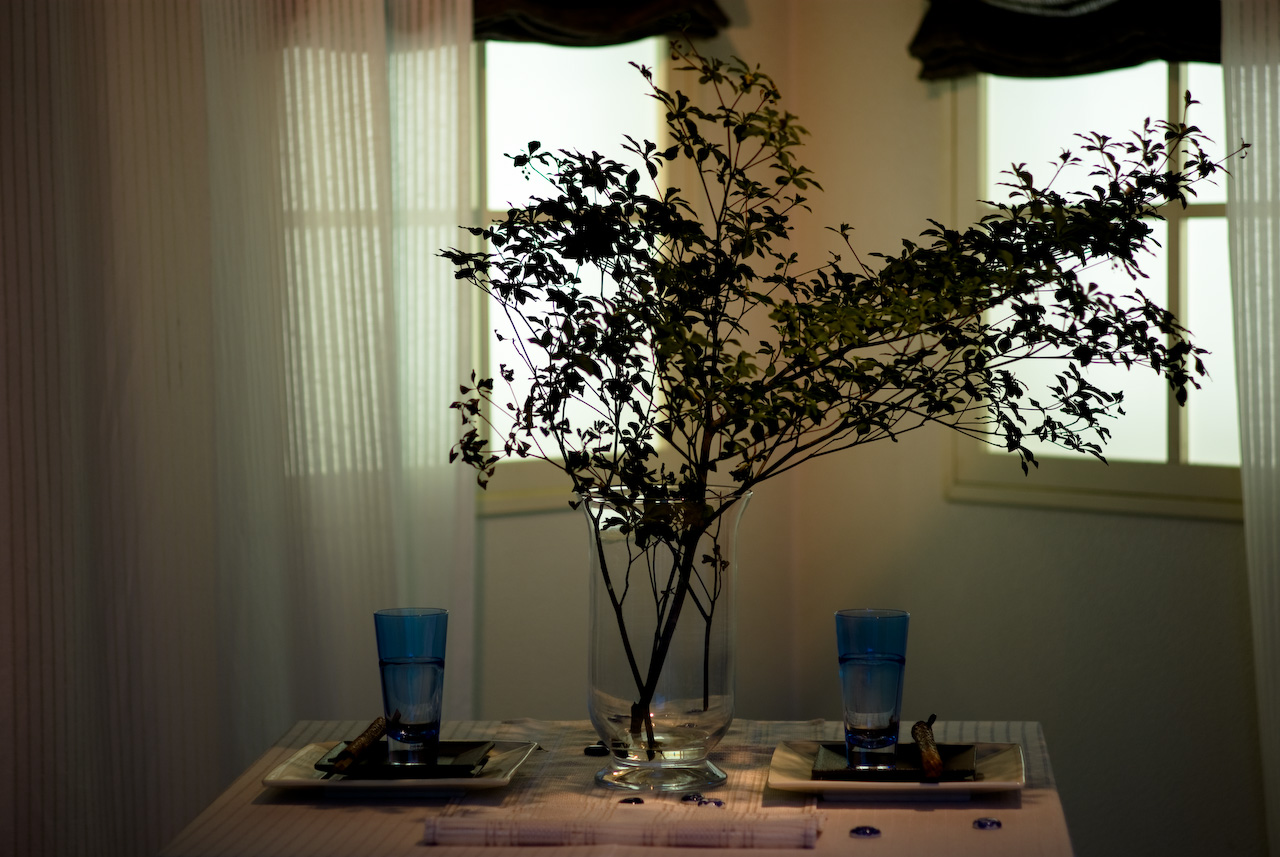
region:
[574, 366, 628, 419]
leaf on the plant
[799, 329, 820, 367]
leaf on the plant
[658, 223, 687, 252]
leaf on the plant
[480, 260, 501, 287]
leaf on the plant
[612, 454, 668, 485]
leaf on the plant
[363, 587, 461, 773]
blue glass on the tray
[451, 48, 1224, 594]
tree in a vase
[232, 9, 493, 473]
sheer white curtain on the window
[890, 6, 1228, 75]
valance on top of the window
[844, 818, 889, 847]
purple rock on the table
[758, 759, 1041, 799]
white tray on the table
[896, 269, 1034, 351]
leaves on the tree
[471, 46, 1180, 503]
picture taken during the day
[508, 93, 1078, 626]
tree stems in the vase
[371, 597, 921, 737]
two blue glasses on the table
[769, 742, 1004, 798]
the plates are square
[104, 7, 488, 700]
white long curtains hang in front of the window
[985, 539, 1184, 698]
the wall is white in color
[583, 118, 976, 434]
the branches are full of leaves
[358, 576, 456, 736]
Blue glass cup on the table.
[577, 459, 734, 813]
White vase with flowers in it.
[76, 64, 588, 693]
White curtain covering the window.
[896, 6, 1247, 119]
Dark covering over the window.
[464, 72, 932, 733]
Thin green plants in the glass vase.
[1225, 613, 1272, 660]
Bottom of the curtains by the window.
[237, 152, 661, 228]
White paneling across the window.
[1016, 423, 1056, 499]
Small green leaf on the bottom of branch.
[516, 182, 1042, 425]
Leaves are green color.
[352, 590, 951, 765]
Glass is blue color.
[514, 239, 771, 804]
Plant is in the jar.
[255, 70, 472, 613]
Screen is white color.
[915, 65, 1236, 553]
Window is white color.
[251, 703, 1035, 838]
Plate is in the table.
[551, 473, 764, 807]
Jar is filled with water.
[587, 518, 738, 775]
Stick is brown color.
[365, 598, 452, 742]
a blue water glass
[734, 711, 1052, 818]
a white square plate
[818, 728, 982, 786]
a small black plate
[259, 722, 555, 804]
a white square plate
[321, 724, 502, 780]
a small black plate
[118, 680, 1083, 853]
a small white table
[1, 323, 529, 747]
white curtains on a window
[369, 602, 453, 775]
Clear blue drinking glass, 3/4 of the way full of water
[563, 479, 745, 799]
Large glass plant vase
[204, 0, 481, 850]
Striped see through white window curtain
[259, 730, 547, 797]
Large square dinner plate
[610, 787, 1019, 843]
Shiny black stones on table as decoration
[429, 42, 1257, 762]
Large tree like plant with many twigs and branches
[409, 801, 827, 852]
Pinkish colored towel, rolled up legnthwise.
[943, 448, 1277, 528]
Thick white lower window sill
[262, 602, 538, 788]
drinking glass on square plate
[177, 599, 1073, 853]
two place setting on table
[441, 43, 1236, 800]
plant in glass vase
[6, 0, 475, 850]
panel of hanging white drapes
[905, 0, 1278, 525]
valance on top of window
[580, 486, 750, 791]
stems of plant in glass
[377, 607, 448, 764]
glass with blue tint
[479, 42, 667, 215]
sunlight in window pane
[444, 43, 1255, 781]
a large branch in a vase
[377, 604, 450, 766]
a tall blue cup